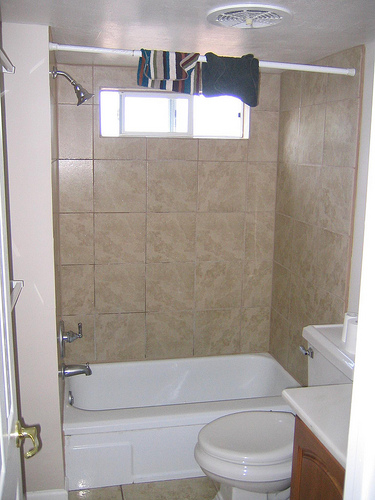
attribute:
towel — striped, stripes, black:
[125, 43, 263, 116]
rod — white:
[61, 37, 360, 87]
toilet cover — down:
[206, 415, 305, 466]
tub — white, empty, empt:
[66, 358, 298, 408]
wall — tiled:
[80, 152, 258, 331]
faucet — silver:
[62, 362, 112, 387]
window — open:
[96, 83, 251, 160]